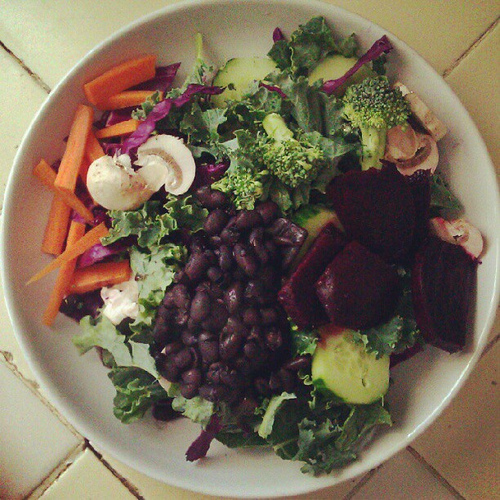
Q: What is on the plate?
A: A salad.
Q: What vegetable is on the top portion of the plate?
A: Broccoli.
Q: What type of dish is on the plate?
A: A salad.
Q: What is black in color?
A: The beans.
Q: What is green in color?
A: The lettuce.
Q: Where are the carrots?
A: On the plate.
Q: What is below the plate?
A: Floor.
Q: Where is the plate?
A: Under the vegetables.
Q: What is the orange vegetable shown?
A: Carrots.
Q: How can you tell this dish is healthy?
A: Salad and vegetables.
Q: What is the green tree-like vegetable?
A: Broccoli.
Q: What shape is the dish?
A: Round.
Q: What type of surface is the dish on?
A: Tile.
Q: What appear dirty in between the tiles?
A: The grout.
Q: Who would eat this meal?
A: A human.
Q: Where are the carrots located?
A: Left side of salad.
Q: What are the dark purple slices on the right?
A: Beets.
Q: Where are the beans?
A: Next to beets.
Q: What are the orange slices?
A: Carrots.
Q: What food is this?
A: Fresh vegetable salad.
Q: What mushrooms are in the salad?
A: Champignons.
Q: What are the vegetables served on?
A: White plate.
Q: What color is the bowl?
A: White.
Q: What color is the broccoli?
A: Green.